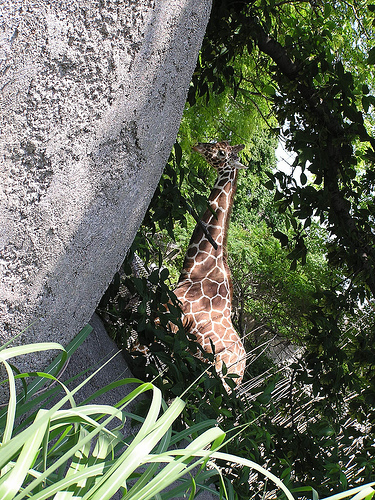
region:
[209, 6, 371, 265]
green leaves on branch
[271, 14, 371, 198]
light of daytime sky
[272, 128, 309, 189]
patch of light blue sky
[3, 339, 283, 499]
long thin plant leaves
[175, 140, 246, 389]
side of standing giraffe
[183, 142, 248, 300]
head and neck of giraffe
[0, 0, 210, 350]
chipped surface of cement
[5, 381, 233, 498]
sun reflection on green blades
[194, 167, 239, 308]
mane on giraffe neck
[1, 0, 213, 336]
light and shadow of cement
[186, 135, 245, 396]
giraffe grazing from tree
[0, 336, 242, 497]
grass growing in front of stone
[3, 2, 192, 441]
stones in the foreground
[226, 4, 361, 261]
tree branch hanging in middle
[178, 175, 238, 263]
long neck of giraffe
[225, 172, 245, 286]
brown mane down giraffe's neck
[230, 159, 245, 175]
white ear of giraffe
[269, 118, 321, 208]
sky peaking through tree branches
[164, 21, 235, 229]
area giraffe is grazing from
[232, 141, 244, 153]
small horn of giraffe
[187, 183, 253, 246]
neck of the giraffe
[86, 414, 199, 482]
light hitting the grass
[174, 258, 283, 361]
body of the giraffe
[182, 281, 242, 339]
brown spots on the giraffe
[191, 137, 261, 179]
head of the giraffe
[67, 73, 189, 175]
rock next to the giraffe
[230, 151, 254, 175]
ear of the giraffe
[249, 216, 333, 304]
trees in the distance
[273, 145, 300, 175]
sky above the trees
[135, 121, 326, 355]
one giraffe in the photo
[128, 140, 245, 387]
brown and white giraffe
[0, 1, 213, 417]
very large round gray rock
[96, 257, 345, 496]
green weeds growing next to the rock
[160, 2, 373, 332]
green trees growing in the background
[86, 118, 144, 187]
rounded indents in the rock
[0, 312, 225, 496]
gray concrete sidewalk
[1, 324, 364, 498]
tall green grass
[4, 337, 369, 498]
sunlight reflecting on the blades of grass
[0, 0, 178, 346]
sunlight on the side of the rock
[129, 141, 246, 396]
sunlight on a giraffe's back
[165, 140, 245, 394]
Giraffe in the wild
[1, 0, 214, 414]
Textured large grey boulder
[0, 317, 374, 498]
Tall native grass plant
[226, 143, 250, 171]
Giraffe ears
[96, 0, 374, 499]
Bushy green leaf plant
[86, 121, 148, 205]
Coarse textured area on rock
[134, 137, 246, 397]
Giraffe looking for food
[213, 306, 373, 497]
Plant with white spikes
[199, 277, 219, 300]
Spot on a giraffe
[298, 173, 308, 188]
Green leaf from a plant